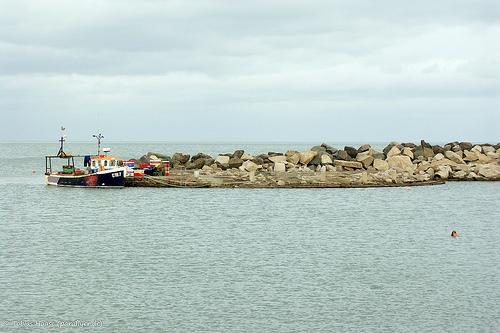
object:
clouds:
[191, 48, 348, 70]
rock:
[319, 154, 334, 165]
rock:
[287, 153, 302, 163]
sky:
[324, 8, 496, 111]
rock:
[176, 153, 190, 163]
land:
[122, 145, 247, 182]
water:
[0, 198, 129, 295]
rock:
[355, 151, 376, 164]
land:
[256, 140, 420, 165]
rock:
[187, 157, 208, 167]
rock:
[172, 153, 180, 158]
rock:
[188, 155, 204, 170]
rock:
[230, 149, 247, 159]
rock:
[386, 155, 414, 175]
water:
[193, 246, 401, 310]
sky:
[206, 21, 302, 78]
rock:
[374, 156, 390, 172]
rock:
[384, 155, 412, 165]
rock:
[365, 165, 376, 173]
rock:
[384, 167, 396, 179]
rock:
[345, 145, 358, 157]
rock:
[445, 149, 466, 163]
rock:
[415, 155, 426, 162]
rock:
[334, 158, 365, 168]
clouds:
[0, 0, 66, 68]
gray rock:
[337, 149, 349, 159]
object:
[451, 229, 458, 237]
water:
[0, 250, 500, 331]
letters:
[110, 168, 122, 179]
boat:
[43, 166, 126, 188]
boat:
[85, 153, 120, 171]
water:
[106, 227, 388, 319]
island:
[457, 138, 499, 181]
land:
[340, 172, 436, 185]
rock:
[332, 160, 364, 168]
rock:
[300, 152, 314, 164]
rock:
[270, 158, 288, 173]